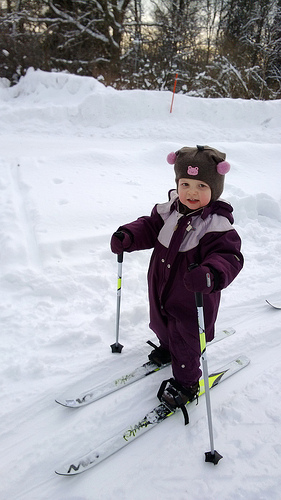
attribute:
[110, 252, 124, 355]
pole — ski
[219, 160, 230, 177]
ball — pink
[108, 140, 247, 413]
child — small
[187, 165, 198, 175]
bear head — small, pink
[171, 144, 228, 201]
hat — child's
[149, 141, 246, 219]
head — girl's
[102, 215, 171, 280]
gloves — purple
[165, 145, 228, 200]
winter cap — small child's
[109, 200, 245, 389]
snow suit — small child's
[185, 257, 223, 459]
skipole. — left-hand, silver, yellow, black